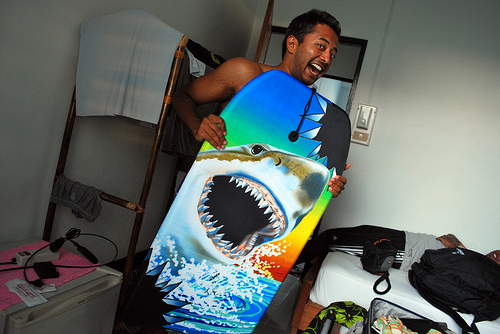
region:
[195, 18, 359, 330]
man is holding a surfboard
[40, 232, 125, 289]
the cord is black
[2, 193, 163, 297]
the cord is black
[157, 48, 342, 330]
a shark boogie board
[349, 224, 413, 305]
a black camera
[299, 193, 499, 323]
a person laying on a bed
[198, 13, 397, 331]
a man holding a boogie board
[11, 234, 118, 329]
a white power strip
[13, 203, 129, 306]
black cords on a power strip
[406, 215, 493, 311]
a black backpack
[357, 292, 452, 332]
a opened suitcase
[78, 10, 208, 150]
a white towel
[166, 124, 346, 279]
a shark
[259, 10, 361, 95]
the head of a man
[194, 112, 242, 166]
the hand of a man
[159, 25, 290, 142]
the arm of a man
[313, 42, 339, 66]
the nose of a man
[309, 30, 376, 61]
the eyes of a man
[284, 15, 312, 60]
the ear of a man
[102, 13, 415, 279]
a man holding up a surfboard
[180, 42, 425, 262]
a shark on a surfboard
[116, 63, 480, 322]
a colorful surfboard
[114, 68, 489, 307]
a man laying on the bed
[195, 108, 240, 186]
right hand on man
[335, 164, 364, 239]
left hand on man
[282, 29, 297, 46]
right ear on man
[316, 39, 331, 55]
right eye on man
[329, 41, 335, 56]
left eye on man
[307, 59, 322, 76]
big mouth on man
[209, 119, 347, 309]
large shark on board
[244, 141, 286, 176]
right eye on shark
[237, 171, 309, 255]
big teeth on shark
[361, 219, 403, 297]
camera bag on bed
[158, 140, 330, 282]
a drawn shark in the ocean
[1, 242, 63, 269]
a power strip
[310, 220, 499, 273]
a person laying on a bed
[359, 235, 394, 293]
a black and grey camera case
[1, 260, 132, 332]
a small mini white fridge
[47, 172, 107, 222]
a pair of grey shorts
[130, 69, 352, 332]
a surfing foam board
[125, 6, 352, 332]
a guy posing with a foam board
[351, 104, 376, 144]
a wall light switch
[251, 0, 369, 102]
the top of a open door